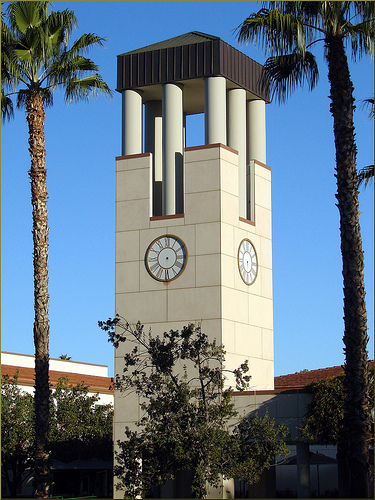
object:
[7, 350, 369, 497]
building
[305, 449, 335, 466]
umbrella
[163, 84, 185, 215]
column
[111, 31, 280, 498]
clock tower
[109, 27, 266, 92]
roof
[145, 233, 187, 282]
clock face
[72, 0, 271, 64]
sky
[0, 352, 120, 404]
building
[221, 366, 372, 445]
building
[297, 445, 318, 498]
pillar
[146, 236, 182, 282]
clock face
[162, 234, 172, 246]
roman numeral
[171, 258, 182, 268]
roman numeral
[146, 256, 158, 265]
roman numeral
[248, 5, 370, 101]
palm tree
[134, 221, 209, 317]
clock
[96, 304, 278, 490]
tree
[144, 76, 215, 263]
pillar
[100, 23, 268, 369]
tower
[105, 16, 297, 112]
roof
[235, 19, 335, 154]
leaf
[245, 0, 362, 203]
tree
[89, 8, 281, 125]
roof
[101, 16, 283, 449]
tower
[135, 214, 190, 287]
clock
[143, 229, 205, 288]
clock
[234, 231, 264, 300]
clock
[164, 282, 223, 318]
brick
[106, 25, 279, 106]
pyramid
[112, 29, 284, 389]
tower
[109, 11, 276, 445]
tower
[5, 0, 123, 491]
tree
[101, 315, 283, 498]
tree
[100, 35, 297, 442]
building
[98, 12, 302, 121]
roof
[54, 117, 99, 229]
sky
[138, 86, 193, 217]
pillar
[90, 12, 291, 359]
tower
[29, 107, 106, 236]
sky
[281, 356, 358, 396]
roof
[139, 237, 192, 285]
clock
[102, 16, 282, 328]
tower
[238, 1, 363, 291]
tree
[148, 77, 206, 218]
column